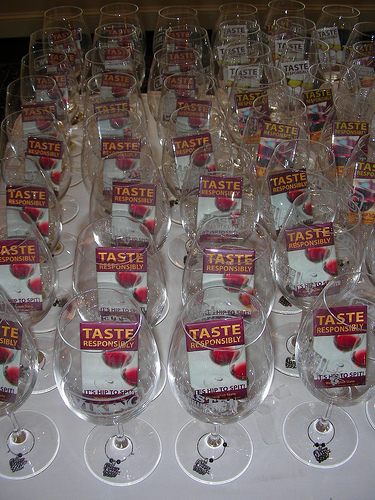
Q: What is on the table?
A: Wine glasses.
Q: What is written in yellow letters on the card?
A: Taste Responsibly.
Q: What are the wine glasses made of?
A: Clear glass.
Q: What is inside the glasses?
A: Chocolate bars.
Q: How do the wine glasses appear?
A: Clean.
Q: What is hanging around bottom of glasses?
A: Wine charms.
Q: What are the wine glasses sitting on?
A: Table.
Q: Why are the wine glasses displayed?
A: For tasting.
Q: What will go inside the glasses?
A: Wine.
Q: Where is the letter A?
A: In the cup.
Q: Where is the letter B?
A: On the sign.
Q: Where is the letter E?
A: On the sign.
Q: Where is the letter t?
A: In the cup.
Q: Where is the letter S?
A: In the cup.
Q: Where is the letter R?
A: In the cup.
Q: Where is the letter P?
A: In the cup.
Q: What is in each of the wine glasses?
A: A magnet.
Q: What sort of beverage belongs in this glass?
A: Wine.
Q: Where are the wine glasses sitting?
A: In a row on a table.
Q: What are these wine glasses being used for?
A: A wine tasting.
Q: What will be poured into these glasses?
A: Wine.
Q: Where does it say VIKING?
A: On the glass.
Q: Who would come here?
A: Wine tasters.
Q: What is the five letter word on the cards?
A: TASTE.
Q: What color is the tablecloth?
A: White.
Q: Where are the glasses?
A: On a table.